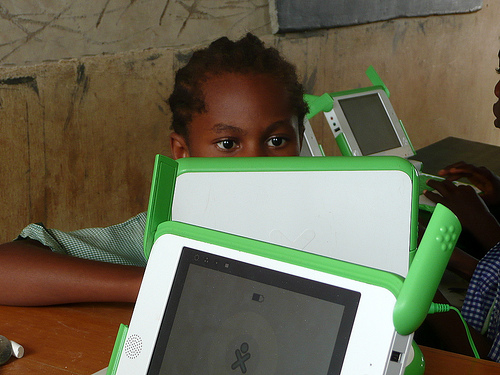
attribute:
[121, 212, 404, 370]
case — green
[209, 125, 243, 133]
eye brow — bushy, black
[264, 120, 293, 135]
eye brow — bushy, black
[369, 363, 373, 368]
spot — small, black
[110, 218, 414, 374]
tablet — green, white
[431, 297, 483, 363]
cord — electrical, green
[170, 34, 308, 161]
head — short, brown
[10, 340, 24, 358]
chalk — white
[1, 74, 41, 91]
dent — small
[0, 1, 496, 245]
wall — brown, cement, tan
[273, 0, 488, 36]
screen — white, blackened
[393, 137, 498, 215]
table — brown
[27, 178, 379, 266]
shirt — green, white, gree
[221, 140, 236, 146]
eye — brown, black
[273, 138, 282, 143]
eye — brown, black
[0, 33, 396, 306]
boy — young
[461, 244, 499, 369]
shirt — blue, white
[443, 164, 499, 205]
hand — typing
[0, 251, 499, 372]
table — wooden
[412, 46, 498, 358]
kid — young, typing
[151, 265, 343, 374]
cpu screen — gray